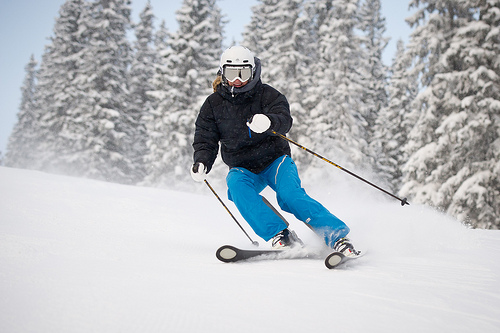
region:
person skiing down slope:
[182, 39, 377, 279]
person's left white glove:
[247, 112, 280, 138]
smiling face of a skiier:
[223, 64, 252, 90]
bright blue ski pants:
[218, 157, 352, 248]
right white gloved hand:
[192, 157, 209, 183]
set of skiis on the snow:
[213, 237, 370, 277]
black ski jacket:
[191, 80, 293, 172]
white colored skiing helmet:
[216, 43, 258, 70]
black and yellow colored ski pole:
[249, 116, 419, 211]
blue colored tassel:
[247, 124, 252, 141]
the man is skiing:
[158, 9, 393, 304]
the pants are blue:
[220, 151, 370, 270]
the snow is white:
[69, 221, 156, 296]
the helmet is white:
[213, 37, 263, 97]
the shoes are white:
[288, 227, 398, 288]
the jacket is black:
[182, 61, 303, 204]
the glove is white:
[242, 100, 279, 150]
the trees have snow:
[47, 13, 159, 180]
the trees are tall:
[44, 7, 155, 211]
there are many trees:
[32, 10, 417, 196]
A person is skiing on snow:
[152, 40, 464, 300]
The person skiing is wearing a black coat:
[165, 78, 322, 185]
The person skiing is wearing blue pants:
[193, 153, 375, 265]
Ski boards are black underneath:
[202, 234, 380, 294]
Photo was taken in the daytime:
[7, 3, 498, 318]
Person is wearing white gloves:
[179, 105, 296, 228]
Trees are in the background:
[25, 11, 498, 201]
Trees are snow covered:
[23, 11, 499, 190]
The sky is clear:
[3, 8, 456, 119]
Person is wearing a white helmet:
[201, 40, 278, 97]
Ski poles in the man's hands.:
[200, 113, 408, 246]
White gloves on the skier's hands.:
[190, 110, 270, 181]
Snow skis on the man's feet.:
[212, 238, 373, 268]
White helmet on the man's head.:
[217, 45, 254, 73]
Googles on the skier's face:
[215, 61, 256, 82]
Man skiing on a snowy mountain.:
[187, 46, 409, 268]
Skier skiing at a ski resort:
[13, 42, 476, 312]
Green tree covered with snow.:
[15, 3, 147, 182]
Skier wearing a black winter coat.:
[64, 32, 434, 292]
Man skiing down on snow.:
[141, 28, 435, 308]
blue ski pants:
[220, 153, 357, 243]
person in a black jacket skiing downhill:
[162, 30, 435, 280]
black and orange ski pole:
[269, 125, 421, 207]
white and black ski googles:
[216, 61, 258, 86]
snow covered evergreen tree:
[402, 0, 498, 237]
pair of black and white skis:
[212, 242, 391, 274]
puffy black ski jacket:
[180, 80, 310, 175]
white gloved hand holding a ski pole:
[187, 161, 216, 186]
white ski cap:
[217, 40, 264, 67]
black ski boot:
[263, 227, 305, 249]